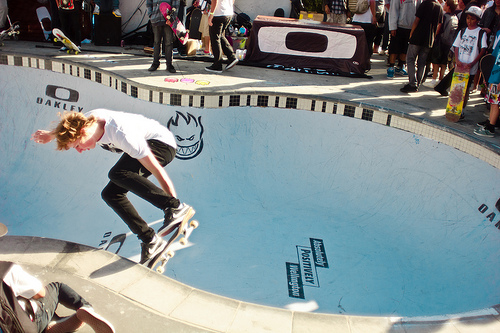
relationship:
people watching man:
[324, 1, 500, 139] [31, 108, 191, 265]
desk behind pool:
[243, 14, 369, 81] [0, 54, 499, 316]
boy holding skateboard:
[448, 5, 489, 120] [445, 62, 471, 125]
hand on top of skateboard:
[455, 60, 461, 68] [445, 62, 471, 125]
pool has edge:
[0, 54, 499, 316] [1, 54, 499, 170]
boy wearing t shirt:
[448, 5, 489, 120] [453, 25, 488, 75]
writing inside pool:
[285, 236, 330, 300] [0, 54, 499, 316]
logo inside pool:
[36, 84, 84, 116] [0, 54, 499, 316]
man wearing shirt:
[31, 108, 191, 265] [80, 108, 178, 161]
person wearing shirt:
[206, 1, 240, 73] [209, 0, 234, 19]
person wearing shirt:
[352, 1, 377, 81] [351, 7, 374, 23]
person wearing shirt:
[388, 0, 417, 79] [388, 1, 418, 31]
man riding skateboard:
[31, 108, 191, 265] [147, 205, 200, 274]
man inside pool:
[31, 108, 191, 265] [0, 54, 499, 316]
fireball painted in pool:
[164, 110, 205, 160] [0, 54, 499, 316]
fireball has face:
[164, 110, 205, 160] [174, 135, 200, 156]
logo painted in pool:
[95, 232, 127, 254] [0, 54, 499, 316]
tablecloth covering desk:
[246, 15, 369, 75] [243, 14, 369, 81]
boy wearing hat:
[448, 5, 489, 120] [463, 6, 484, 21]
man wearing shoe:
[31, 108, 191, 265] [139, 236, 167, 262]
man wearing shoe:
[31, 108, 191, 265] [159, 202, 191, 230]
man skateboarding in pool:
[31, 108, 191, 265] [0, 54, 499, 316]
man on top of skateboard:
[31, 108, 191, 265] [147, 205, 200, 274]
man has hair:
[31, 108, 191, 265] [52, 111, 96, 150]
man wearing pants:
[31, 108, 191, 265] [101, 140, 180, 244]